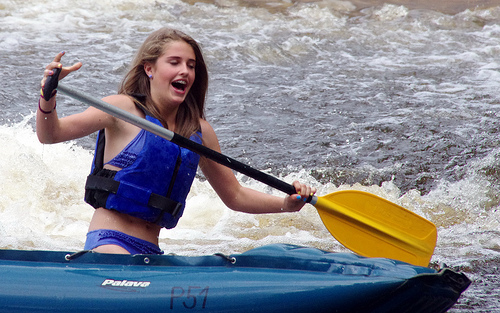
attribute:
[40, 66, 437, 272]
paddle — yellow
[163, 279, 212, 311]
writing — p51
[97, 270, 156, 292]
writing — white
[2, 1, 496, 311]
water — running quickly